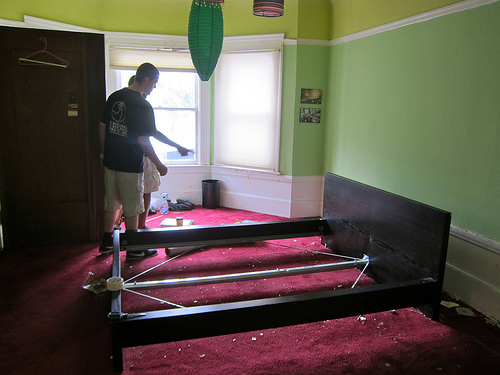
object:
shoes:
[98, 237, 159, 261]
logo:
[128, 251, 148, 257]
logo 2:
[106, 246, 114, 249]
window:
[108, 69, 200, 162]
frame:
[105, 212, 451, 375]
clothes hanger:
[16, 37, 71, 68]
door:
[0, 26, 111, 246]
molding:
[252, 0, 500, 68]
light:
[185, 0, 224, 81]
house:
[0, 0, 500, 375]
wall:
[0, 0, 500, 235]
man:
[98, 62, 169, 261]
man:
[115, 75, 196, 229]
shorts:
[103, 167, 146, 218]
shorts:
[143, 156, 161, 193]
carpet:
[0, 205, 495, 375]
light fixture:
[252, 1, 285, 18]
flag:
[382, 83, 486, 142]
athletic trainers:
[97, 61, 195, 261]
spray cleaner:
[160, 192, 169, 214]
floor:
[147, 203, 285, 230]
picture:
[300, 88, 323, 104]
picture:
[298, 108, 320, 124]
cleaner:
[82, 190, 500, 375]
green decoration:
[188, 0, 225, 82]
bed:
[102, 171, 455, 375]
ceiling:
[3, 0, 500, 33]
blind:
[218, 52, 275, 167]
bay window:
[105, 45, 202, 165]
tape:
[106, 276, 124, 291]